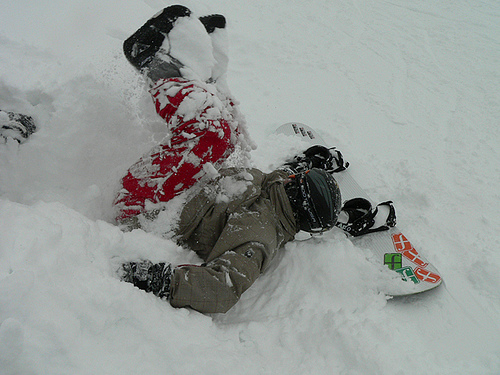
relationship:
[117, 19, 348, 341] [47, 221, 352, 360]
man on snow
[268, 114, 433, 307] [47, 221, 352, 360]
snowboard on snow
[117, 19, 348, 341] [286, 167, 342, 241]
man wearing helmet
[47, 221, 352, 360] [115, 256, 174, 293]
snow on glove